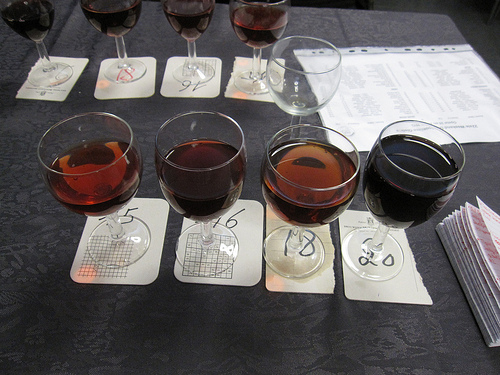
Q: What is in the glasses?
A: Alcohol.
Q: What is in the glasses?
A: Wine.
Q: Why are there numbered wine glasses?
A: For a wine-tasting expo.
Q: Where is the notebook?
A: On a table.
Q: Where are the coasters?
A: Under the wine glasses.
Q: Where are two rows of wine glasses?
A: On table.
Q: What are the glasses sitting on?
A: Coasters.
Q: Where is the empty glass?
A: Behind first row of glasses.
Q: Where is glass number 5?
A: First row, first glass on left.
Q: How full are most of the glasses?
A: Half full.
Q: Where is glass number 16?
A: First row, second glass.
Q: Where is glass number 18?
A: First row, third glass.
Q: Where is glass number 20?
A: First row, last glass.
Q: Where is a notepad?
A: Lower right hand corner.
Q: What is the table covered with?
A: Black table cloth.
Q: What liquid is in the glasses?
A: Wine.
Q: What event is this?
A: Wine tasting.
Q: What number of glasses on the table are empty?
A: 1.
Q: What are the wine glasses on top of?
A: A piece of paper.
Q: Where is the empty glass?
A: In between the two rows of full glasses.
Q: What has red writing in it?
A: The notebook.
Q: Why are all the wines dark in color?
A: The are red wines.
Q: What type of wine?
A: Red.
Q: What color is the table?
A: Black.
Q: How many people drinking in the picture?
A: Zero.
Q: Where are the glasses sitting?
A: On a table.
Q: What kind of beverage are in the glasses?
A: Wine.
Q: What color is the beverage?
A: Brown.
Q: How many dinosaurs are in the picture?
A: Zero.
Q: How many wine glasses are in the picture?
A: Nine.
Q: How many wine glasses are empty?
A: One.